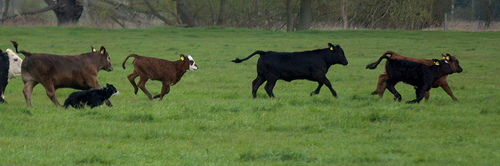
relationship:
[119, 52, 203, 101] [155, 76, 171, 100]
cow has leg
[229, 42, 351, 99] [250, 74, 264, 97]
cow has leg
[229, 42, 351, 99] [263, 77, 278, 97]
cow has leg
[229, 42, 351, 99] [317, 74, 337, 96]
cow has leg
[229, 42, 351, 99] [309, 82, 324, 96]
cow has leg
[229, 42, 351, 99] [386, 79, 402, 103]
cow has leg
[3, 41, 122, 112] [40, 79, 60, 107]
cow has leg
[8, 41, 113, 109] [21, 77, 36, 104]
cow has leg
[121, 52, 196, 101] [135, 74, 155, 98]
cow has leg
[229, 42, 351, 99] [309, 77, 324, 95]
cow has leg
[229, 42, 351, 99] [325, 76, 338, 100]
cow has leg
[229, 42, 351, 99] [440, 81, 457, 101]
cow has leg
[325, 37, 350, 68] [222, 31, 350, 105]
head on cow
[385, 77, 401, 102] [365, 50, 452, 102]
leg of cow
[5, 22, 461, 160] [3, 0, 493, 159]
large pasture on a farm